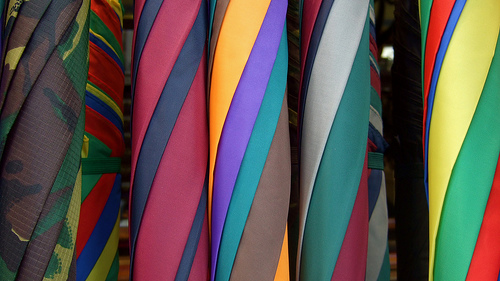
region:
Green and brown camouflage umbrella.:
[1, 0, 79, 280]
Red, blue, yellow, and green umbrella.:
[81, 0, 127, 279]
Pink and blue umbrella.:
[132, 6, 210, 279]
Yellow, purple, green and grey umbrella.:
[210, 0, 295, 280]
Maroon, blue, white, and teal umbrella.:
[297, 0, 368, 279]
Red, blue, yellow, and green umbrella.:
[418, 1, 498, 279]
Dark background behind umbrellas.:
[382, 0, 423, 275]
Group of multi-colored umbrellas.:
[3, 4, 498, 274]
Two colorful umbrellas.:
[131, 1, 293, 278]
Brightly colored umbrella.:
[413, 0, 496, 279]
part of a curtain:
[358, 175, 369, 185]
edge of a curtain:
[328, 113, 343, 126]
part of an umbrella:
[232, 150, 248, 171]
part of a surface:
[120, 145, 133, 167]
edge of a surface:
[395, 188, 408, 205]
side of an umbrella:
[33, 128, 53, 149]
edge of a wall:
[228, 175, 240, 192]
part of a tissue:
[240, 185, 246, 193]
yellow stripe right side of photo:
[424, 0, 497, 280]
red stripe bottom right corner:
[465, 154, 498, 279]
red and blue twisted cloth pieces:
[122, 0, 207, 279]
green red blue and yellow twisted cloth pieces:
[415, 2, 499, 274]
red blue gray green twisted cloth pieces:
[294, 2, 380, 279]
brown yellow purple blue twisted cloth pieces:
[202, 0, 304, 280]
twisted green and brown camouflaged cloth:
[1, 2, 81, 279]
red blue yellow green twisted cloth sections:
[67, 0, 128, 276]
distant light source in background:
[372, 42, 397, 69]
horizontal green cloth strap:
[76, 152, 130, 177]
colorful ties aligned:
[5, 9, 487, 277]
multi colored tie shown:
[213, 12, 301, 279]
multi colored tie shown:
[133, 10, 207, 277]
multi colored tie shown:
[96, 11, 128, 279]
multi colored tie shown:
[11, 10, 86, 274]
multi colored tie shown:
[296, 1, 354, 277]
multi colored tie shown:
[421, 5, 486, 272]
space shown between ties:
[383, 23, 428, 277]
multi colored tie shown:
[371, 18, 403, 280]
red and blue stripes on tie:
[133, 6, 233, 279]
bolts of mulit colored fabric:
[1, 1, 493, 279]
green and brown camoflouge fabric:
[8, 0, 84, 275]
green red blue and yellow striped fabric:
[71, 0, 127, 279]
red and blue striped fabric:
[130, 0, 205, 279]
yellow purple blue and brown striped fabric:
[207, 0, 289, 280]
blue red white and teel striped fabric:
[297, 0, 387, 280]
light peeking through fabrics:
[380, 37, 396, 67]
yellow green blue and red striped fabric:
[422, 6, 495, 277]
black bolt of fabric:
[396, 0, 426, 280]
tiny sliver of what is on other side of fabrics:
[384, 70, 394, 280]